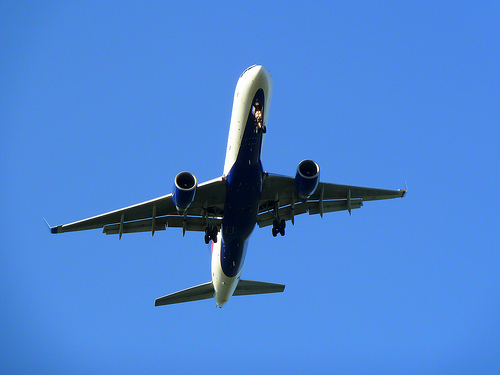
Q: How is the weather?
A: Clear.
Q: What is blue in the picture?
A: The sky.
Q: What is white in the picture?
A: A plane.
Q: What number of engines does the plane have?
A: Two.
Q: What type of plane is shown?
A: A commercial jet.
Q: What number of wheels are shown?
A: Three.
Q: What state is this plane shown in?
A: Taking off state.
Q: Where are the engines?
A: On plane.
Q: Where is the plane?
A: In sky.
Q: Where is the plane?
A: In sky.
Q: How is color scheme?
A: Blue and white.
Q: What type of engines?
A: Jet.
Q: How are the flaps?
A: Down.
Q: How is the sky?
A: Cloudless.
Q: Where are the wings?
A: On plane.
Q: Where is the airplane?
A: In air.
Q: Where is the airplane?
A: In the air.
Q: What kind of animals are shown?
A: None.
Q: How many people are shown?
A: None.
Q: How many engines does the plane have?
A: Two.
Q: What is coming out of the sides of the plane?
A: Wings.